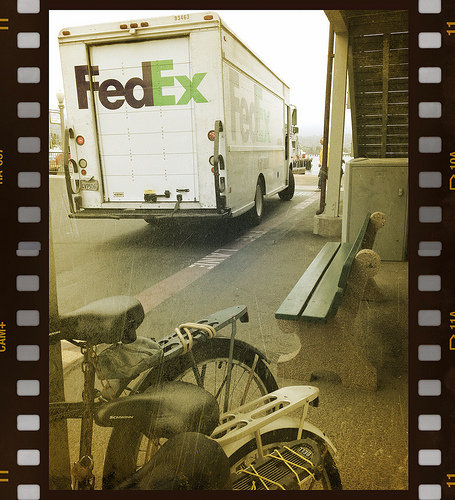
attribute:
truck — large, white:
[56, 35, 258, 247]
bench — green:
[286, 229, 381, 323]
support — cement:
[293, 345, 368, 383]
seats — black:
[65, 310, 193, 439]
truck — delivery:
[55, 10, 300, 232]